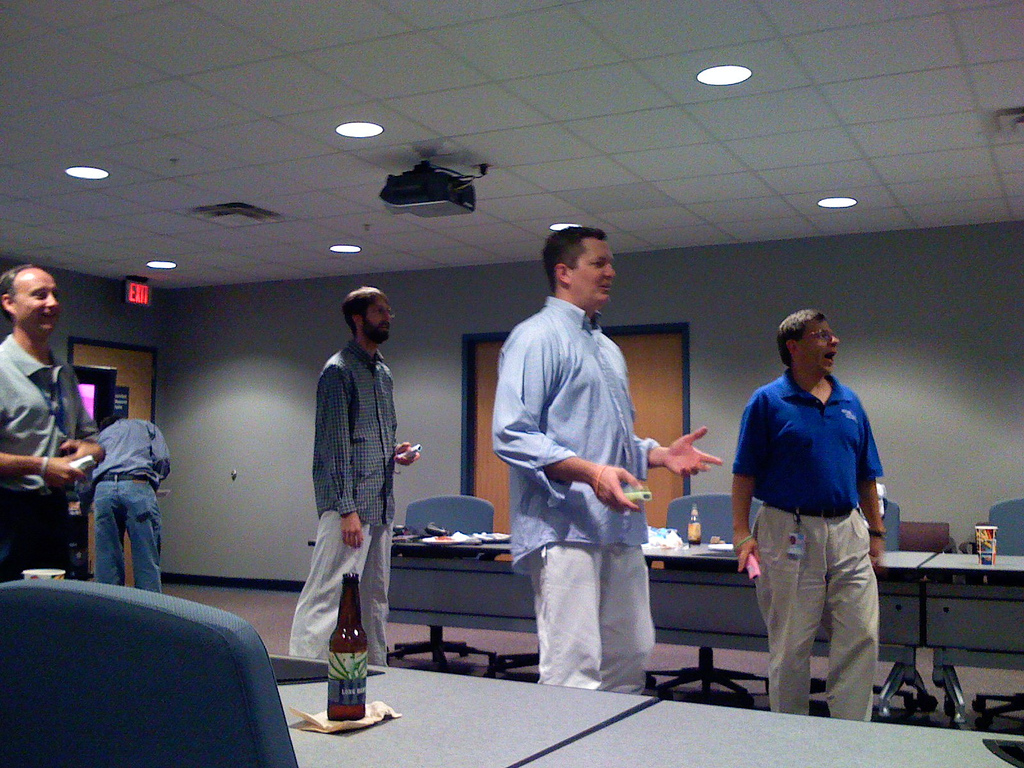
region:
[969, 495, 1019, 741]
a chair that you sit in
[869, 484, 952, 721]
a chair that you sit in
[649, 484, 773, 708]
a chair that you sit in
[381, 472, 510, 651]
a chair that you sit in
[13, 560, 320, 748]
a chair that you sit in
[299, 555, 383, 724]
a bottle for holding liquid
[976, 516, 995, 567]
a vessel made for drinking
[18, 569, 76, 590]
a vessel made for drinking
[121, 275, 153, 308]
EXIT sign above the window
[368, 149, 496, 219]
Projector hanging from the ceiling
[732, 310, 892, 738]
Man wearing a blue polo shirt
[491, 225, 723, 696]
Man holding a white Wii remote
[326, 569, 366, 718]
Beer bottle sitting on the table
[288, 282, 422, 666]
Man standing below the projector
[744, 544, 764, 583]
Wii remote is pink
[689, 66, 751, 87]
Recessed lighting in the ceiling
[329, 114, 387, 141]
Recessed lighting in the ceiling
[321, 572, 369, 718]
beer bottle sitting on a brown napkin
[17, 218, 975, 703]
a group of men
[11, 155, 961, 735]
the men are standing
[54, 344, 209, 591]
man is bending oveer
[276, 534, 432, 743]
a brown beer bottle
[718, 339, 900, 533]
a blue polo shirt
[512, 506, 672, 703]
a pair of white pants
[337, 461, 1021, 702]
a row of desks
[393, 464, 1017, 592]
a row of chairs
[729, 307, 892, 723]
Man wearing a blue shirt.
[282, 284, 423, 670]
Man wearing a gray shirt.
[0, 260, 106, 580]
Man wearing a gray shirt.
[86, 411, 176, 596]
Man wearing a blue shirt.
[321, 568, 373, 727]
Brown glass bottle with blue and white label.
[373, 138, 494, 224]
Black and silver projector hanging from ceiling.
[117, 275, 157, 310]
Red and black lid up EXIT sign.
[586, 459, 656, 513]
Right hand holding a Wii remote.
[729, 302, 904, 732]
The man in the dark blue collar shirt with short sleeves.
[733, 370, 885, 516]
The dark blue collar shirt the man is wearing.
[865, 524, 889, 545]
The watch on the wrist of the man in the dark blue shirt.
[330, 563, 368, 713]
The brown bottle on the table.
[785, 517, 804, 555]
The name tag pin to the man's khaki pants.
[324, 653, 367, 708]
The label on the brown bottle that is on the table.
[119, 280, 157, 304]
The EXIT sign above the door.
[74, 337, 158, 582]
The door beneath the EXIT sign.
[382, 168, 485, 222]
The projector device on the ceiling.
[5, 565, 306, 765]
The chair behind the table where the brown bottle is placed.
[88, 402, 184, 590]
The man closest to the door with the EXIT sign above it.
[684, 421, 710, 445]
person has a finger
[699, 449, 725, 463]
person has a finger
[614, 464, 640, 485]
person has a finger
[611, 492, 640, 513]
person has a finger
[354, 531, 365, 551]
person has a finger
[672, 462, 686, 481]
person has a finger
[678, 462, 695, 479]
person has a finger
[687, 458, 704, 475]
person has a finger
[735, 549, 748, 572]
person has a finger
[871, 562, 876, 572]
person has a finger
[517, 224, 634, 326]
the head of a man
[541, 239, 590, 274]
the hair of a man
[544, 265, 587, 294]
the ear of a man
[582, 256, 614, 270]
the eye of a man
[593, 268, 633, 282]
the nose of a man